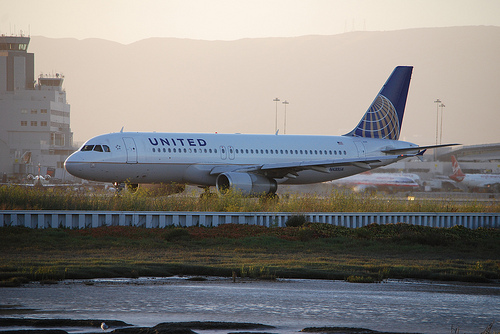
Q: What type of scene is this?
A: Outdoor.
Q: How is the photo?
A: Clear.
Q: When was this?
A: Daytime.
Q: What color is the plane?
A: White.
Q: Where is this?
A: Airport.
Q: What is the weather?
A: Sunny.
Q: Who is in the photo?
A: No one.